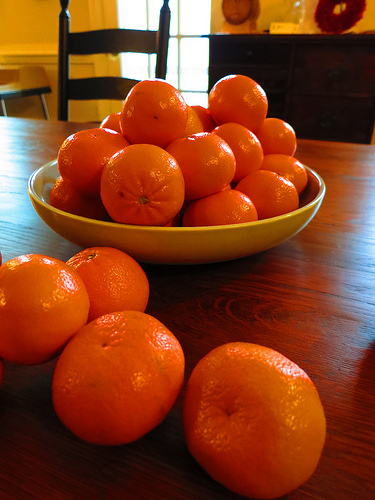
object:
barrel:
[220, 0, 262, 33]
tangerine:
[51, 74, 307, 224]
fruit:
[51, 75, 308, 224]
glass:
[274, 1, 319, 25]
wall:
[2, 4, 53, 42]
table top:
[282, 252, 361, 303]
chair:
[0, 65, 52, 120]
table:
[0, 117, 375, 500]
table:
[1, 117, 100, 264]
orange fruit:
[208, 71, 268, 133]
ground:
[305, 90, 338, 129]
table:
[292, 147, 374, 410]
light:
[1, 118, 43, 258]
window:
[117, 6, 209, 99]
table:
[2, 65, 51, 117]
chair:
[57, 1, 172, 123]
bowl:
[28, 157, 327, 264]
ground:
[190, 43, 228, 67]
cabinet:
[209, 23, 374, 144]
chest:
[199, 33, 375, 145]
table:
[341, 185, 372, 253]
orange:
[51, 74, 305, 225]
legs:
[0, 94, 50, 120]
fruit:
[0, 245, 328, 499]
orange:
[0, 243, 327, 500]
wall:
[0, 0, 375, 57]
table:
[330, 140, 372, 498]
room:
[2, 1, 375, 500]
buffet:
[202, 15, 374, 42]